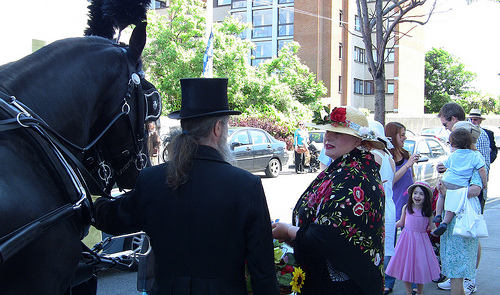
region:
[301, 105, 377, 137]
she is wearing a flowered hat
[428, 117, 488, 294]
the woman is holding a child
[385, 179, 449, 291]
the girl is laughing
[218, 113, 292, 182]
a car on the road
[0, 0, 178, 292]
the man is holding a horse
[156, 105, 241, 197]
his hair is long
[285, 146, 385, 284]
her shawl is flowered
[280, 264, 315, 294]
the sunflower is yellow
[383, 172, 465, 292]
a young child in a pink dress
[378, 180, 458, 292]
young child in a pink outfit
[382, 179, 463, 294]
a young girl in a pink outfit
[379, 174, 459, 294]
young girl with a pink dress and hat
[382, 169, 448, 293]
a young girl dressed in pink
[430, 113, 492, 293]
a lady holding a child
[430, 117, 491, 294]
a lady holding a young child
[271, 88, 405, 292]
a lady wearing a floral hat and shawl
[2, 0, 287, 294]
a man holding his horse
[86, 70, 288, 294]
a bearded man with a hat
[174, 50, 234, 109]
man has top hat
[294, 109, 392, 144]
woman has tan hat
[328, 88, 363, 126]
red flower on hat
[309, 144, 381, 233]
red and black shawl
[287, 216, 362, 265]
woman has black jacket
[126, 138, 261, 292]
man has black jacket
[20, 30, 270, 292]
man holds black horse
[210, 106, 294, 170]
black car behind man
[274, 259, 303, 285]
yellow sunflower near woman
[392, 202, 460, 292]
girl has pink dress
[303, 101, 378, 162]
a woman wearing a hat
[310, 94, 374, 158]
a hat with a red flower on it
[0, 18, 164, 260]
a large black horse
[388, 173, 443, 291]
a young girl wearing a pink dress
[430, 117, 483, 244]
a woman holding a young child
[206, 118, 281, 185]
a car parked on the side of a street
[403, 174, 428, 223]
a young girl with brown hair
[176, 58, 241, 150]
a man wearing a black hat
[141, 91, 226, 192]
a man with long hair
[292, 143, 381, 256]
a woman wearing a shawl with a floral print